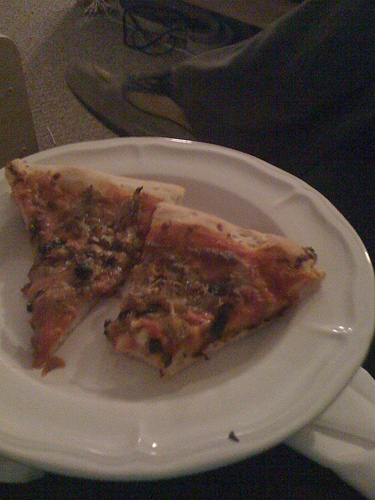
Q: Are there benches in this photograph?
A: No, there are no benches.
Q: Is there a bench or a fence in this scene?
A: No, there are no benches or fences.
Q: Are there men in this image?
A: No, there are no men.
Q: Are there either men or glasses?
A: No, there are no men or glasses.